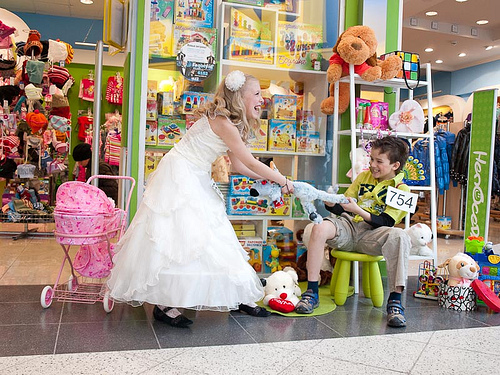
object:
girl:
[103, 68, 296, 327]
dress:
[109, 114, 267, 309]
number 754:
[384, 185, 421, 215]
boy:
[294, 136, 418, 328]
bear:
[261, 262, 302, 314]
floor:
[1, 233, 499, 374]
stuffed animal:
[318, 24, 402, 115]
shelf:
[330, 50, 442, 298]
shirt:
[328, 51, 371, 75]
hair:
[370, 136, 408, 163]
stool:
[328, 247, 388, 309]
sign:
[174, 41, 217, 82]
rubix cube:
[379, 49, 425, 81]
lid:
[470, 277, 499, 312]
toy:
[251, 161, 350, 226]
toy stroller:
[40, 172, 136, 312]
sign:
[463, 87, 496, 245]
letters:
[467, 146, 492, 240]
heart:
[268, 296, 296, 311]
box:
[386, 98, 425, 135]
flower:
[392, 109, 413, 126]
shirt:
[103, 132, 123, 165]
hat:
[46, 39, 69, 65]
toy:
[437, 252, 481, 289]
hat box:
[437, 281, 479, 313]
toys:
[149, 1, 328, 274]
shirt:
[340, 168, 413, 224]